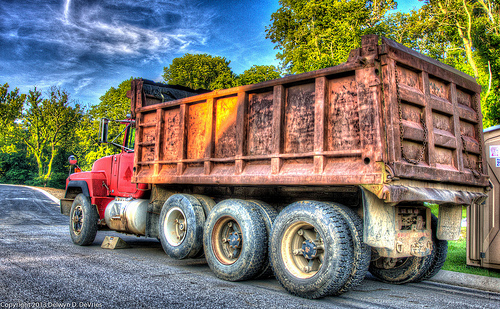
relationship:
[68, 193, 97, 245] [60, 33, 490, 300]
tire of dump truck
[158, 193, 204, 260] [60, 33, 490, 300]
tire of dump truck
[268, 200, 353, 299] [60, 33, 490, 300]
tire of dump truck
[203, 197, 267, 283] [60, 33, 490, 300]
tire of dump truck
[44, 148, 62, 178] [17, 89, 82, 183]
trunk of tree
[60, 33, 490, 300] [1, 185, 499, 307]
dump truck on road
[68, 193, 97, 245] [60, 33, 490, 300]
tire on dump truck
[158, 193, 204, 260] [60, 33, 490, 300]
tire on dump truck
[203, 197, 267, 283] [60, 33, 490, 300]
tire on dump truck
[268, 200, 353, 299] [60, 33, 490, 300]
tire on dump truck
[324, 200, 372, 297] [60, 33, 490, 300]
tire on dump truck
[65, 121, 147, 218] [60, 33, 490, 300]
truck cab of dump truck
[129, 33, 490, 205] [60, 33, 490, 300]
bed of dump truck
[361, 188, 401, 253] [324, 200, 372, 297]
flap of tire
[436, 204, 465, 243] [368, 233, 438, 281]
flap of tire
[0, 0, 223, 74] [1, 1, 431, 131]
clouds in sky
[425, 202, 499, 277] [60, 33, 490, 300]
grass near dump truck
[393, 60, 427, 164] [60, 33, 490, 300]
chains on dump truck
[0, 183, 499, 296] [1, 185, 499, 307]
curb on road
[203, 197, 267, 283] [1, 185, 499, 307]
tire sitting on road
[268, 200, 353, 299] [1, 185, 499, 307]
tire sitting on road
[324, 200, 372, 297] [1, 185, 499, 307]
tire sitting on road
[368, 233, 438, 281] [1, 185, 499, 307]
tire sitting on road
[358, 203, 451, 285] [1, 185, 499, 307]
tire sitting on road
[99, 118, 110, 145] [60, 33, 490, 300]
mirror on dump truck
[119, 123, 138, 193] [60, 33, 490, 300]
door of dump truck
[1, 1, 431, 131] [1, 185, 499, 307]
sky above road